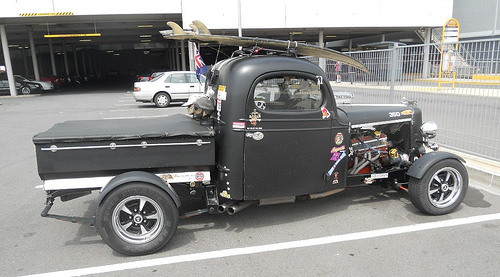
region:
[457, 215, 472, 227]
part of a wheel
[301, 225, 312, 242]
edge of a pavement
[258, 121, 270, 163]
part of a door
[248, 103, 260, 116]
part of a window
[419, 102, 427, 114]
part of a rail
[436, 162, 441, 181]
edge of a wheel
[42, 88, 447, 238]
black truck is parked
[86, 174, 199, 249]
black wheels on truck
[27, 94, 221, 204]
black bed on truck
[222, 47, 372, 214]
black door on truck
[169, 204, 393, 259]
parking lot is light grey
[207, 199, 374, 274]
white line on lot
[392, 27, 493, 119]
metal fence near truck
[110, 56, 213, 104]
white car is parked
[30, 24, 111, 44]
yellow bar in garage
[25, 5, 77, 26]
yellow and black warning bar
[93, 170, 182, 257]
the tire of a truck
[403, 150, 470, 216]
the tire of a truck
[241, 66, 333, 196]
the door of a truck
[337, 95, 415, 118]
the hood of a truck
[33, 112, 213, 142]
the bed of a truck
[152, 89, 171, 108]
the tire of a car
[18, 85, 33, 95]
the tire of a car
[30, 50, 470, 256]
a parked black truck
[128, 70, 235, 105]
a parked white car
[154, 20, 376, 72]
a surfboard on a truck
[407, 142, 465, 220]
tire in front of a truck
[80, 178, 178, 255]
tire in the back of a truck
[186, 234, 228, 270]
white line on a parking lot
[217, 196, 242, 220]
double mufflers on a truck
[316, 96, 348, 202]
stickers on the side of a truck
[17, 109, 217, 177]
covered back of a pick up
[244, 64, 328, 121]
window on the side of a truck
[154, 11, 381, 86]
surf board on the top of a truck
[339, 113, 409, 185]
exposed engine on the side of a truck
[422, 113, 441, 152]
chrome headlight on the front of a truck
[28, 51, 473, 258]
classic black colored truck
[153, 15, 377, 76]
surfboard on a black truck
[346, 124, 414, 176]
visible engine on an old truck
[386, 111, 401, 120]
number on the hood of a truck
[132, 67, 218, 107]
white car with a black stripe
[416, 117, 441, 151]
chrome headlight on a black truck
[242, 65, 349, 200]
passenger door on a truck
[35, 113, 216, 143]
bed cover on a truck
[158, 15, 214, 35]
rudder on a surfboard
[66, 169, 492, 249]
shadow under a truck